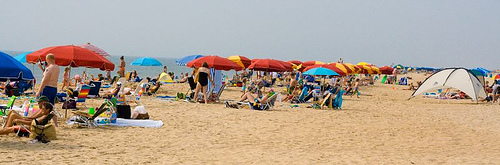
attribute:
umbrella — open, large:
[28, 40, 122, 74]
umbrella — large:
[186, 54, 244, 75]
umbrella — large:
[188, 51, 237, 72]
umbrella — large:
[126, 53, 171, 73]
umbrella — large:
[301, 65, 348, 79]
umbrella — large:
[350, 58, 380, 76]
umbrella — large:
[295, 56, 327, 68]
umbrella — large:
[161, 51, 201, 71]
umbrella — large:
[22, 42, 116, 72]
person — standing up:
[30, 53, 60, 127]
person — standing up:
[115, 53, 127, 74]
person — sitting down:
[61, 62, 73, 91]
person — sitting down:
[133, 76, 160, 92]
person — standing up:
[192, 64, 213, 96]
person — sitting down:
[221, 89, 281, 112]